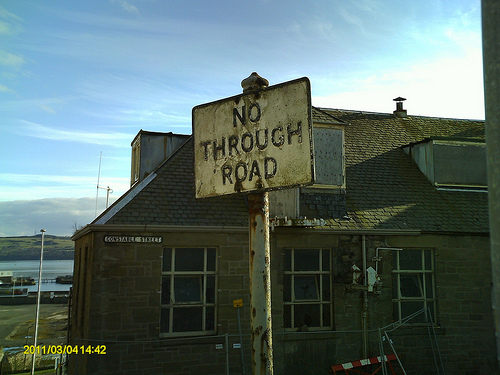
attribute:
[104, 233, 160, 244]
sign — old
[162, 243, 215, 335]
window — wooden, broken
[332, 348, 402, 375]
construction sign — orange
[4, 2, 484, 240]
sky — blue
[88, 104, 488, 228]
roof — brown, brow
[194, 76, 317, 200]
sign — metal, old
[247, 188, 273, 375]
pole — rusty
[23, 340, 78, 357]
date stamp — yellow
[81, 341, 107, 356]
time stamp — yellow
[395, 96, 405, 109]
chimney — metal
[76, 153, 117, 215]
antenna — metal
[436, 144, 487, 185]
window — boarded up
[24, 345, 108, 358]
date and time stamp — yellow